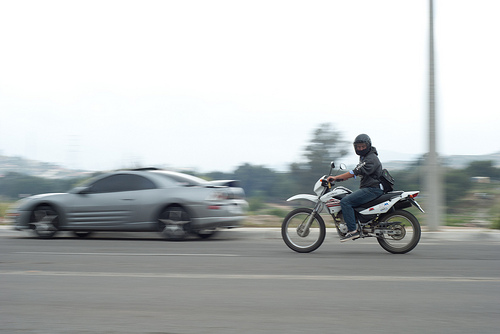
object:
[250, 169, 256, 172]
leaves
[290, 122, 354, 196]
tree